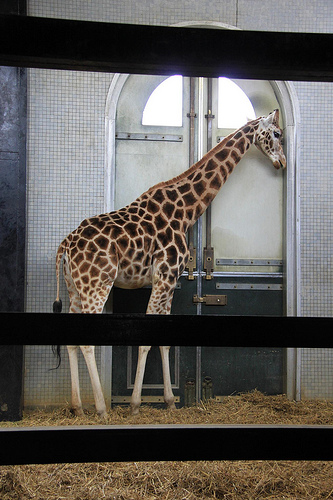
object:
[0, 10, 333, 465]
fence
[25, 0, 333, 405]
wall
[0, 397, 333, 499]
floor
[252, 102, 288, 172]
head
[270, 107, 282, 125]
horn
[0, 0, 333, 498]
giraffe pen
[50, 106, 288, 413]
giraffe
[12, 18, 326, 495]
enclosure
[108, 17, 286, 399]
door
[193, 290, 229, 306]
bolt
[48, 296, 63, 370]
tip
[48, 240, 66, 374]
tail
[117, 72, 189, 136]
window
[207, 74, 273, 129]
window